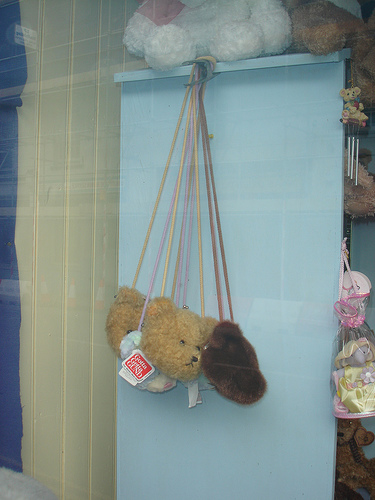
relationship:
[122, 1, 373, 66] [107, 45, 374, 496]
animals on top of shelf unit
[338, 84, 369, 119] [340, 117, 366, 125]
bear on stick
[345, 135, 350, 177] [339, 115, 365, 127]
chime on stick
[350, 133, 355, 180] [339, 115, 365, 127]
chime on stick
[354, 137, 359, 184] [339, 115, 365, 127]
chime on stick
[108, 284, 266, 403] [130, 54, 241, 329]
stuffed animals on rope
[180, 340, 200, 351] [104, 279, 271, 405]
eyes on animals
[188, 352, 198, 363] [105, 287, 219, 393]
nose on animal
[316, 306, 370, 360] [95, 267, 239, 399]
hat on stuffed animal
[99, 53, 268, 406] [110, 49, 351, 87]
windchime on shelf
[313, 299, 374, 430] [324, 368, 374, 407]
animal on bag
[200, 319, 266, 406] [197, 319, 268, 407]
head on bear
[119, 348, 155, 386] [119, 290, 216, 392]
tag on bear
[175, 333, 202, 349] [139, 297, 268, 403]
eyes on bear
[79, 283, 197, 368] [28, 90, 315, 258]
purse on wall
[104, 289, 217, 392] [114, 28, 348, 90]
purse on shelf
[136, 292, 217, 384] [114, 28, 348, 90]
purse on shelf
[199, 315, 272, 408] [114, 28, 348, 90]
purse on shelf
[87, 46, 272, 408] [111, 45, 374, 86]
purses on shelf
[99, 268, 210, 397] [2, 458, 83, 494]
animal near ground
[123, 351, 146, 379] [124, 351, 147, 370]
tag has words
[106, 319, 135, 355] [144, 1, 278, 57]
legs of teddy bear